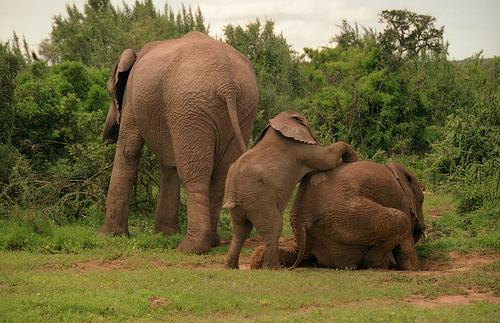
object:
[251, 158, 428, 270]
elephant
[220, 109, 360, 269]
elephant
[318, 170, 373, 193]
back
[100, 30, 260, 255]
elephant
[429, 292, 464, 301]
patch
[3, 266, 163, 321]
grass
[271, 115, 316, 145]
ear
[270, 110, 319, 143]
head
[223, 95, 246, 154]
tail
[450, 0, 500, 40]
sky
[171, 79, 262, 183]
hindquarters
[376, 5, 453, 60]
tree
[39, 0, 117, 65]
tree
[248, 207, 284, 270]
leg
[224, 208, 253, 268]
leg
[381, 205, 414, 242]
knee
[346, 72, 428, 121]
brush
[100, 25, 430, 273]
herd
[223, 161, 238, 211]
tail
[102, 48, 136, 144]
ear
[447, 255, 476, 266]
patch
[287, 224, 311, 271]
tail